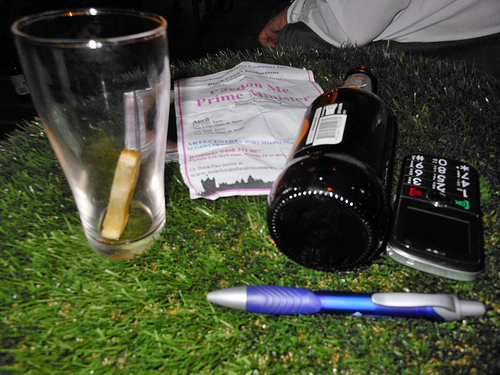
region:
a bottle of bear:
[272, 53, 390, 292]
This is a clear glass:
[6, 9, 191, 306]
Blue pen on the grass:
[200, 280, 495, 327]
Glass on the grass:
[7, 5, 175, 262]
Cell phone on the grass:
[380, 149, 489, 285]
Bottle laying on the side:
[260, 61, 403, 276]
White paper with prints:
[164, 58, 340, 204]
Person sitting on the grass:
[242, 0, 498, 64]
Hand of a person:
[252, 3, 290, 55]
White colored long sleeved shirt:
[283, 1, 498, 49]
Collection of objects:
[7, 3, 490, 328]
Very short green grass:
[0, 43, 499, 374]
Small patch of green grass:
[25, 307, 74, 344]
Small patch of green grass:
[75, 321, 105, 352]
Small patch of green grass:
[106, 320, 167, 374]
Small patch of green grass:
[163, 334, 210, 372]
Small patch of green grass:
[207, 332, 268, 369]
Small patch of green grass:
[303, 334, 340, 364]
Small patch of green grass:
[336, 332, 368, 368]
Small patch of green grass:
[366, 339, 428, 373]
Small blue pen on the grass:
[177, 267, 474, 329]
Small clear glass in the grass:
[4, 2, 196, 285]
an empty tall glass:
[26, 9, 207, 285]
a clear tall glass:
[22, 9, 184, 273]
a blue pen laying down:
[187, 271, 492, 346]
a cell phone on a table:
[392, 120, 499, 339]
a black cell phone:
[396, 143, 498, 267]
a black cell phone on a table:
[393, 141, 499, 313]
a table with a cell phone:
[397, 135, 492, 287]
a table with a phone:
[353, 90, 479, 332]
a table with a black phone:
[379, 96, 496, 263]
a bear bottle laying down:
[209, 25, 446, 361]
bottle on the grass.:
[270, 50, 392, 270]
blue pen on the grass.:
[197, 268, 483, 327]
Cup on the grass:
[11, 6, 176, 253]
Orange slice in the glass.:
[96, 135, 146, 240]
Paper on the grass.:
[171, 57, 324, 209]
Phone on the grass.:
[383, 135, 489, 287]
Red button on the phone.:
[401, 179, 424, 201]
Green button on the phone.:
[451, 191, 472, 212]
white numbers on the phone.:
[405, 148, 474, 202]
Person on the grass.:
[252, 0, 498, 61]